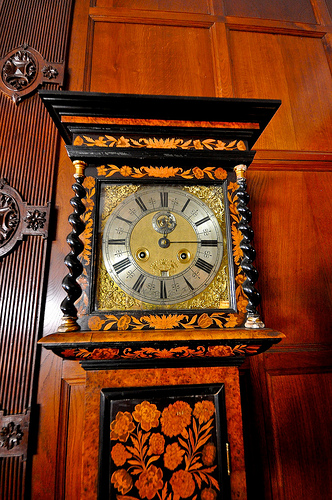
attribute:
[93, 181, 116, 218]
handle — gold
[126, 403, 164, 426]
flower — carved, drawn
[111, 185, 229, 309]
clock — wood, gold, silver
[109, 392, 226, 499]
design — floral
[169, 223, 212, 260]
hands — thin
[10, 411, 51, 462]
hinge — brass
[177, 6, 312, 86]
panel — wood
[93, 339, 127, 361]
carving — wood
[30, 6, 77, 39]
frame — wooden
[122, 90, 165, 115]
board — wooden, brown, new